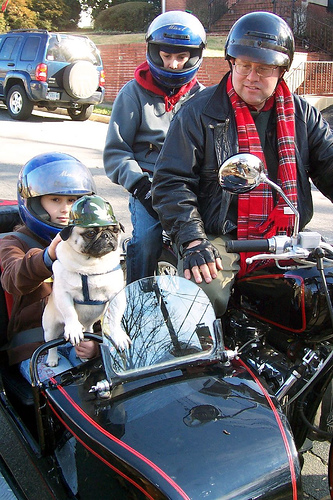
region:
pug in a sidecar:
[40, 194, 137, 370]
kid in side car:
[7, 150, 104, 359]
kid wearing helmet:
[15, 137, 99, 249]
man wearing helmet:
[223, 6, 301, 110]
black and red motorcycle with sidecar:
[3, 175, 329, 482]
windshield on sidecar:
[82, 253, 253, 390]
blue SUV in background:
[4, 21, 105, 124]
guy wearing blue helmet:
[134, 5, 211, 86]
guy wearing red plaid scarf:
[207, 52, 306, 246]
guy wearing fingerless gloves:
[170, 227, 237, 295]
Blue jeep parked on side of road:
[0, 31, 106, 119]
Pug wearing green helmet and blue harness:
[43, 195, 131, 355]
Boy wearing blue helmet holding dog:
[0, 153, 94, 361]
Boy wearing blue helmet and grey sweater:
[108, 7, 210, 242]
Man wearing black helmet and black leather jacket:
[173, 12, 332, 265]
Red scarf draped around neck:
[225, 65, 308, 271]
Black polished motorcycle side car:
[1, 271, 306, 499]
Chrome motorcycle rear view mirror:
[217, 153, 332, 265]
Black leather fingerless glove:
[179, 238, 224, 282]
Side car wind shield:
[98, 272, 229, 379]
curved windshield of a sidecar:
[102, 273, 222, 374]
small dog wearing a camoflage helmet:
[50, 193, 130, 350]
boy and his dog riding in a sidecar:
[4, 153, 134, 388]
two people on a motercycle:
[123, 5, 326, 272]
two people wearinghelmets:
[135, 9, 298, 104]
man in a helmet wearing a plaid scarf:
[215, 9, 305, 159]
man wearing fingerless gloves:
[164, 227, 235, 283]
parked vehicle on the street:
[3, 26, 107, 123]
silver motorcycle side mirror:
[215, 149, 302, 238]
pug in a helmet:
[56, 191, 130, 255]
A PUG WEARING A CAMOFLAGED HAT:
[42, 186, 141, 389]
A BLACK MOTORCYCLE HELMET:
[219, 7, 297, 82]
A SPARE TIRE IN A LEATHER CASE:
[61, 53, 105, 107]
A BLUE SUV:
[0, 21, 111, 125]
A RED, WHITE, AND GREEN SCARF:
[224, 58, 308, 287]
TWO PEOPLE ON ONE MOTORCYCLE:
[96, 4, 332, 320]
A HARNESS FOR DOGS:
[49, 252, 132, 313]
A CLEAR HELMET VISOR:
[19, 157, 102, 202]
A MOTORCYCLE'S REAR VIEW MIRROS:
[213, 150, 304, 236]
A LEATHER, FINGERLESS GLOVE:
[171, 229, 225, 272]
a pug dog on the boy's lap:
[43, 222, 133, 366]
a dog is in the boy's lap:
[43, 222, 132, 368]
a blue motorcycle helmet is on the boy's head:
[15, 151, 96, 236]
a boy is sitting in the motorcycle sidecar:
[3, 146, 104, 498]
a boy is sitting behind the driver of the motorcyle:
[103, 9, 214, 278]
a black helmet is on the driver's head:
[222, 2, 295, 72]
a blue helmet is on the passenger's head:
[143, 6, 207, 87]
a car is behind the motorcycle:
[1, 28, 105, 125]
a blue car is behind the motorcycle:
[143, 8, 207, 88]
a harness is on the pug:
[49, 260, 119, 304]